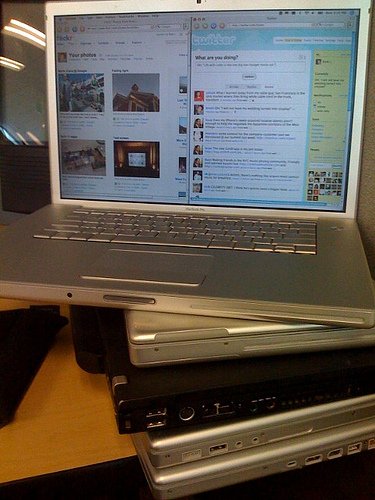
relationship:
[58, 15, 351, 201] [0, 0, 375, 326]
screen of computer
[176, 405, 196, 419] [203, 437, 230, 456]
hole for plug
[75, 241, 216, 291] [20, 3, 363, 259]
touch pad on laptop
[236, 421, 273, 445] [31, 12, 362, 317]
holes on computer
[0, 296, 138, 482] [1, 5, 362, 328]
desk under laptops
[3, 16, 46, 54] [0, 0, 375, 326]
ceiling light left of computer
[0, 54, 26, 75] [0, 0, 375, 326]
ceiling light left of computer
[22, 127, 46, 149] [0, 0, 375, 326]
ceiling light left of computer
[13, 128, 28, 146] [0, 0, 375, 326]
ceiling light left of computer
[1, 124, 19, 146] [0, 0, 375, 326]
ceiling light left of computer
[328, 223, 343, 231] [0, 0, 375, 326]
button on computer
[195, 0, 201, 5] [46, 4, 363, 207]
camera lens on screen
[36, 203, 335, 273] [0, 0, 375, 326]
keyboard on computer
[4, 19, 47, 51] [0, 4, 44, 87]
ceiling light on ceiling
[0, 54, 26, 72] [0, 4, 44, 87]
ceiling light on ceiling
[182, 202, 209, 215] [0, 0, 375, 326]
brand name on computer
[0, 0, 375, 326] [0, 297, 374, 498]
computer on table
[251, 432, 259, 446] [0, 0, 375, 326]
headphone on computer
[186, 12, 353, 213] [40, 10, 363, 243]
twittter page powered on laptop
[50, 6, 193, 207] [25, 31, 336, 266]
flikr page powered on laptop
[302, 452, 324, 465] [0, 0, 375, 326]
slot on side of computer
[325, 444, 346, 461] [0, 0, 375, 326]
slot on side of computer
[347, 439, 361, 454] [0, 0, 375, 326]
slot on side of computer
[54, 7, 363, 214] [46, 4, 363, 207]
website on screen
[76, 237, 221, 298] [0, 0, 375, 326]
mouse pad on computer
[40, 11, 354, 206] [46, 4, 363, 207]
website pulled up on screen